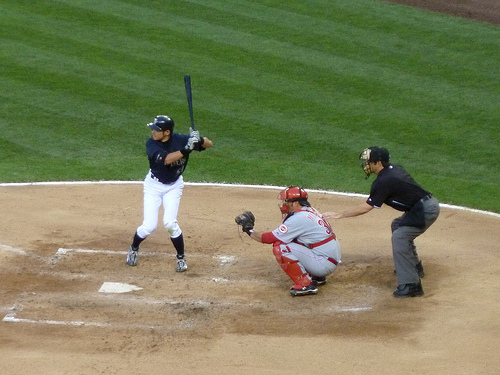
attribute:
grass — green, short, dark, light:
[0, 0, 499, 206]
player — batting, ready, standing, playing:
[128, 116, 212, 273]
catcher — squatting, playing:
[238, 187, 342, 296]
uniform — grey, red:
[264, 213, 343, 279]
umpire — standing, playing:
[323, 147, 441, 297]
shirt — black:
[368, 165, 430, 210]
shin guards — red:
[273, 242, 309, 291]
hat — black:
[370, 146, 390, 167]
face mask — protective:
[358, 147, 374, 177]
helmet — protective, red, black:
[280, 185, 308, 200]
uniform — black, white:
[131, 132, 204, 255]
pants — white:
[138, 169, 185, 240]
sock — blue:
[170, 235, 186, 252]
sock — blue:
[132, 230, 145, 250]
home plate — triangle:
[99, 279, 142, 294]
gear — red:
[279, 187, 312, 296]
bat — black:
[182, 74, 199, 146]